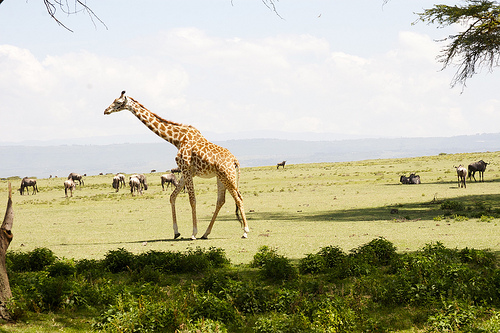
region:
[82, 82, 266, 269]
giraffe walking down the beach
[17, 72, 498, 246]
Animals are grassing.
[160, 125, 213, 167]
Giraffe has brown spots.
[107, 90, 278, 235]
One giraffe is walking.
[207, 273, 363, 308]
Leaves are green color.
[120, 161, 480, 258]
Shadow falls on ground.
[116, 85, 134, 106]
Giraffe has two horns.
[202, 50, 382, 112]
Sky is white color.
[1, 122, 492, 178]
Small foot hill is seen behind the animals.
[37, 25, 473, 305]
Day time picture.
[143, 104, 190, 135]
Giraffe has short hairs on back.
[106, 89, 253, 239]
this is a giraffe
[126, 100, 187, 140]
the giraffe has long neck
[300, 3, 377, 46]
this is the sky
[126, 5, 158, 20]
the sky is blue in color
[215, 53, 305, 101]
these are the clouds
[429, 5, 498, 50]
this is a tree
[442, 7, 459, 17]
the tree has green leaves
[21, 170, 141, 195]
these are the buffaloes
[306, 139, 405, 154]
this is a hill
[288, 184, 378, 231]
this is the ground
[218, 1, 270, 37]
part of the sky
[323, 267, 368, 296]
part of some plants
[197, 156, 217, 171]
stomach of a giraffe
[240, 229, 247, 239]
hoof of a giraffe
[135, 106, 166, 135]
neck of a giraffe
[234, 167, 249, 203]
tail of a giraffe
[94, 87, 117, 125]
mouth of a giraffe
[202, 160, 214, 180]
stomach of a giraffe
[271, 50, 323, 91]
part of some clouds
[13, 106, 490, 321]
animals in a field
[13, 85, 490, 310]
wild animals in a field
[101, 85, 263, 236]
a giraffe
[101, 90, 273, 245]
one lone giraffe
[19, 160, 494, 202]
smaller herd animals in the field with the giraffe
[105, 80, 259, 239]
the giraffe is walking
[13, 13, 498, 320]
it is sunny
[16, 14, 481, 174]
it is a hazy day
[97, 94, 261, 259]
the giraffe is white and brown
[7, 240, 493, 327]
small shrubs at the side of the field